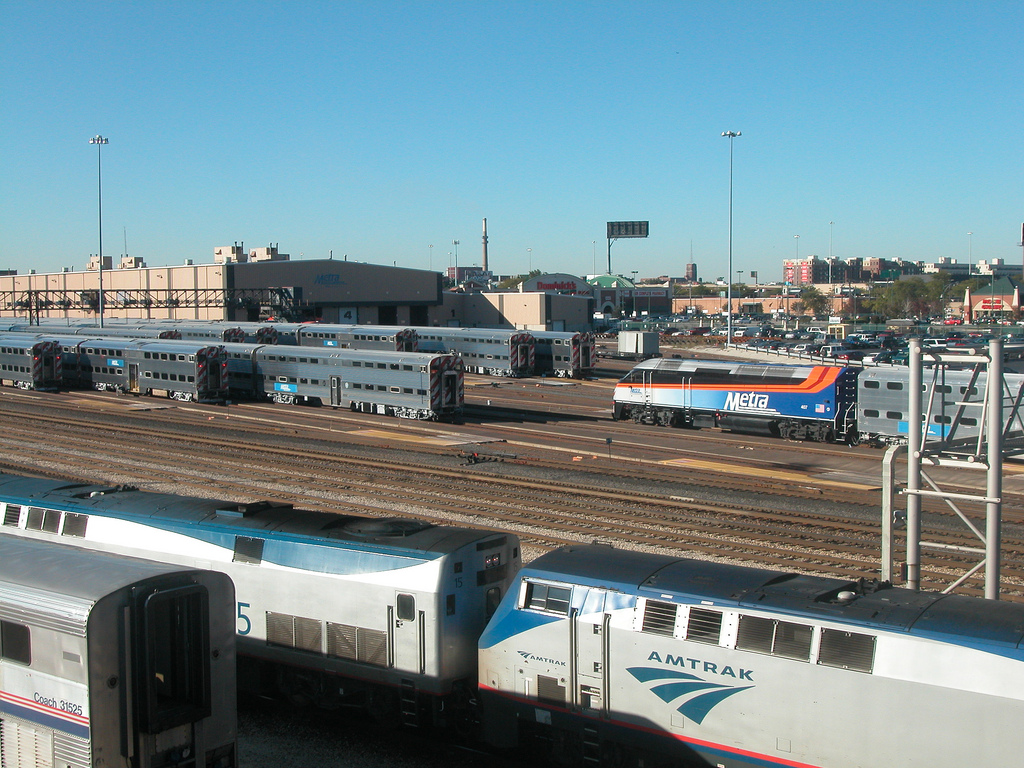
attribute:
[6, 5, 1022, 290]
sky — blue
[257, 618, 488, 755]
window — glass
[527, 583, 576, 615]
window — glass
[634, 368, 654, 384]
window — glass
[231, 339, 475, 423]
train — blue, orange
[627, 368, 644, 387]
window — glass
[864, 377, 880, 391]
window — glass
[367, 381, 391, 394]
window — glass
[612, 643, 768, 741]
logo — blue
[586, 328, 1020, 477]
train — blue, orange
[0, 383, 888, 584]
tracks — brown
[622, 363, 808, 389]
window — glass